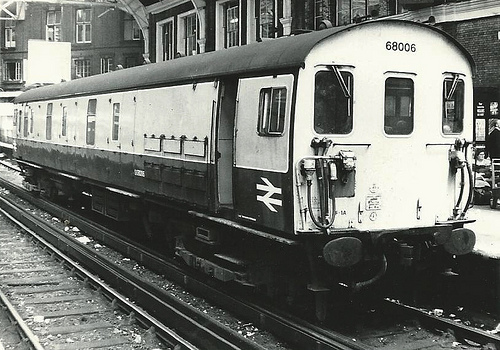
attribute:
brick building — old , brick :
[21, 7, 121, 70]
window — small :
[378, 72, 417, 137]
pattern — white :
[251, 171, 288, 211]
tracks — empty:
[2, 172, 302, 347]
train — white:
[15, 36, 483, 218]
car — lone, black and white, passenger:
[17, 16, 477, 326]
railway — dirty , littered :
[0, 158, 499, 348]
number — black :
[372, 47, 462, 71]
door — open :
[207, 80, 242, 210]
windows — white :
[36, 0, 99, 52]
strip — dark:
[2, 139, 291, 245]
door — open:
[213, 72, 243, 217]